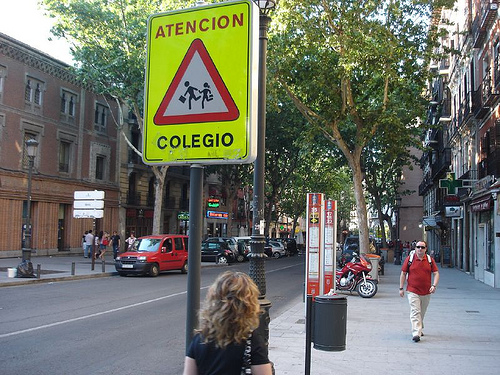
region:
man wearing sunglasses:
[411, 240, 435, 250]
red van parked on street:
[116, 227, 206, 274]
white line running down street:
[14, 290, 151, 350]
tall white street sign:
[63, 178, 135, 231]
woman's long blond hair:
[196, 265, 269, 347]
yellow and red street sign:
[131, 10, 267, 184]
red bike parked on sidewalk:
[332, 253, 382, 301]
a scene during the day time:
[1, 18, 489, 373]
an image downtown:
[2, 18, 490, 373]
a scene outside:
[2, 23, 498, 373]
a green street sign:
[132, 18, 277, 373]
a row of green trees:
[52, 18, 447, 298]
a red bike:
[323, 238, 382, 306]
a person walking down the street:
[382, 225, 452, 354]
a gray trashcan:
[298, 273, 364, 360]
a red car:
[100, 218, 207, 279]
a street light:
[15, 126, 47, 295]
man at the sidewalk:
[388, 219, 445, 346]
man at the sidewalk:
[402, 220, 469, 370]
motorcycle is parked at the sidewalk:
[332, 243, 382, 303]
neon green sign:
[133, 2, 292, 182]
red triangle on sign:
[145, 29, 245, 148]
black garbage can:
[301, 282, 354, 373]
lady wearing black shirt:
[187, 245, 280, 373]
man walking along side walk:
[390, 230, 460, 347]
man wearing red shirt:
[397, 241, 459, 313]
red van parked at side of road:
[99, 232, 211, 287]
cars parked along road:
[185, 222, 326, 267]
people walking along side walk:
[72, 225, 155, 260]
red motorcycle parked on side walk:
[326, 247, 389, 308]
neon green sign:
[111, 0, 288, 187]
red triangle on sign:
[150, 30, 247, 144]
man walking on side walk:
[386, 229, 459, 357]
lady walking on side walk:
[171, 261, 283, 373]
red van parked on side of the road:
[97, 233, 214, 305]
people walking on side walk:
[60, 214, 178, 279]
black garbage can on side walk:
[302, 287, 381, 373]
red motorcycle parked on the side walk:
[336, 234, 397, 326]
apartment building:
[413, 0, 498, 300]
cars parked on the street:
[197, 222, 300, 280]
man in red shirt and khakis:
[398, 240, 440, 339]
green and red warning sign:
[144, 1, 255, 161]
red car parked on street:
[115, 232, 188, 273]